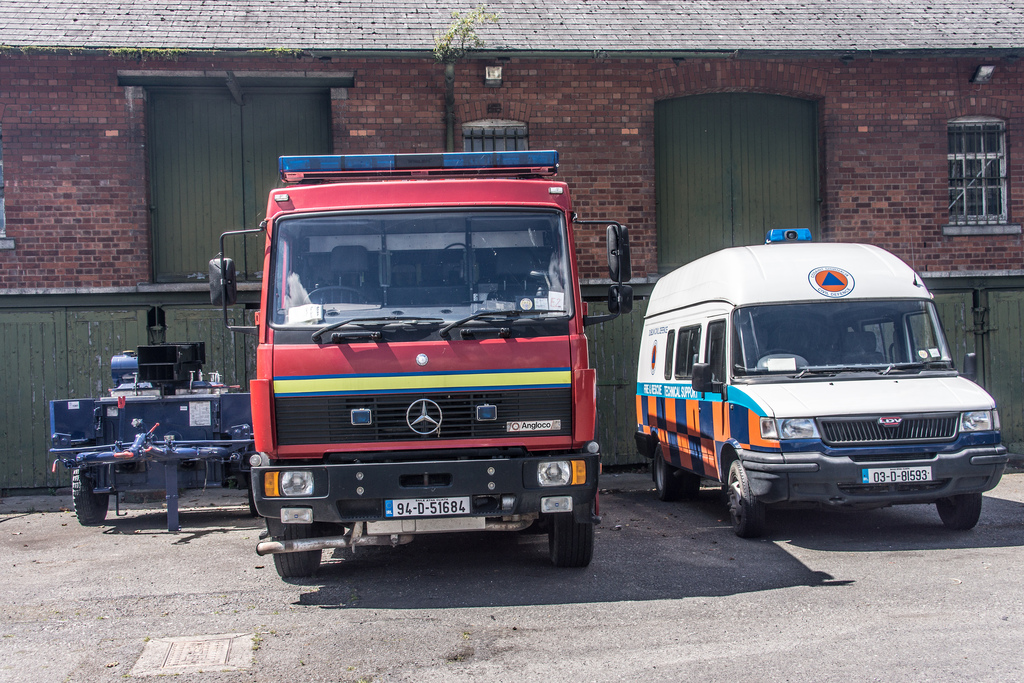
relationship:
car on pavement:
[623, 225, 1009, 633] [0, 471, 1024, 683]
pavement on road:
[525, 605, 576, 678] [525, 605, 576, 678]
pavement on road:
[0, 471, 1024, 683] [573, 596, 627, 651]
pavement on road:
[0, 471, 1024, 683] [621, 605, 661, 662]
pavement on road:
[0, 471, 1024, 683] [675, 616, 714, 677]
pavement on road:
[0, 471, 1024, 683] [721, 600, 778, 673]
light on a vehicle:
[263, 472, 277, 495] [263, 472, 277, 495]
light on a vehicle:
[541, 454, 590, 477] [538, 451, 581, 477]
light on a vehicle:
[778, 211, 810, 247] [778, 211, 810, 247]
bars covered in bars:
[948, 117, 1011, 227] [940, 113, 1008, 225]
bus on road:
[208, 149, 635, 579] [51, 446, 959, 665]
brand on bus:
[406, 399, 442, 435] [204, 147, 635, 584]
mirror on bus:
[571, 211, 635, 317] [204, 147, 635, 584]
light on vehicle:
[289, 466, 313, 489] [289, 466, 313, 489]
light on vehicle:
[349, 401, 381, 424] [227, 115, 617, 563]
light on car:
[773, 420, 821, 439] [632, 229, 1012, 543]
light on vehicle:
[961, 407, 988, 424] [634, 223, 1008, 530]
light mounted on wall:
[474, 58, 506, 84] [0, 9, 1012, 293]